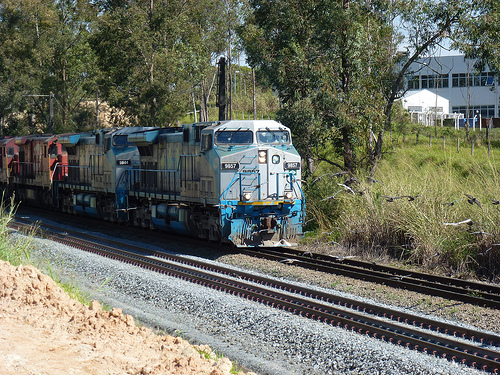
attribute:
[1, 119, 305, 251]
train — here, blue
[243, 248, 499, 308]
tracks — metal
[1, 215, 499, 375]
tracks — metal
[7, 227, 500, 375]
gravel — small, rocky, red-rock, limestone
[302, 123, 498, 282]
grass — green, tall, field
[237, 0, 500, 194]
tree — leaved, green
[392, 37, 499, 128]
building — white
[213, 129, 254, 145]
windshield — clear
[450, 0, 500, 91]
tree — full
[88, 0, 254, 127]
tree — full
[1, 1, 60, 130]
tree — full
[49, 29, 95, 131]
tree — full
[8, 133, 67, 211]
traincar — red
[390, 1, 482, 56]
sky — blue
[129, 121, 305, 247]
train engine — blue, pulling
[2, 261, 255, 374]
hillside — dirt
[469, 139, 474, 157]
post — wood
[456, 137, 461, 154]
post — wood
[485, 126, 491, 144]
post — wood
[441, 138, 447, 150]
post — wood